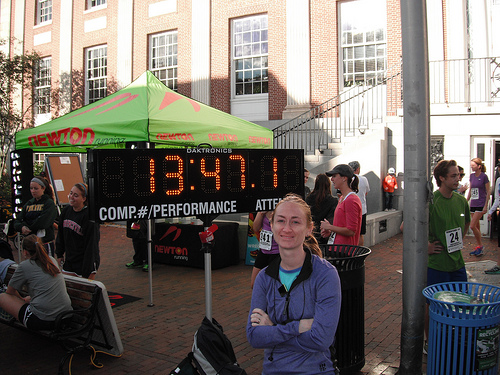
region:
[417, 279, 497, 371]
blue trash on street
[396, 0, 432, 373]
a long grey pole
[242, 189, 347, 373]
a lady in blue sweater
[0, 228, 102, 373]
a lady on bench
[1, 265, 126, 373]
a table leaning on bench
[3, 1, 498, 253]
a brick building with windows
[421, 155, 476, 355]
a man on green shirt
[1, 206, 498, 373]
sidewalk is of bricks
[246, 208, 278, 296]
a lady in purple shirt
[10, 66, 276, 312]
a green umbrella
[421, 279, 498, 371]
A blue trash bin.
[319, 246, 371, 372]
A black trash bin.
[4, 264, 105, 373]
A wooden and metal bench.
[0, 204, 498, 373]
Red bricks on the ground.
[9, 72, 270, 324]
A green and red event tent.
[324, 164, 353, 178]
A dark colored ball cap.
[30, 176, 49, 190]
A grey headband.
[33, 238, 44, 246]
A white hair tie.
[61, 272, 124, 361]
A white foldable table.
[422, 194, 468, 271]
A green short sleeved shirt.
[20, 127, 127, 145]
newton brand name on umbrella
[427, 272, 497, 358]
metal blue trash can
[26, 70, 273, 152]
green sponser umbrella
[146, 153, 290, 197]
time for a racer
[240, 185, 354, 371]
lady with a purple jacket on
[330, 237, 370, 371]
black trash can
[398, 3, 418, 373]
metal pole in brick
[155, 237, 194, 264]
newton brand name on table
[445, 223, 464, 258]
numer 24 racer tag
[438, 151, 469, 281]
man who is a racer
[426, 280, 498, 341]
this is a trash bin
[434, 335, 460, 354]
the bin is blue in color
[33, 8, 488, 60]
this is a building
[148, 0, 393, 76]
these are several windows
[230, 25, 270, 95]
the window is closed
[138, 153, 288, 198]
these are some digits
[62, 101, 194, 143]
this is an umbrella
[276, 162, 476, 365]
these are several people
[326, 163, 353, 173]
this is a cap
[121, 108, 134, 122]
the umbrella is green in color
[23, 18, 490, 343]
a busy street scene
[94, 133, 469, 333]
this young lady is smiling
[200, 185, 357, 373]
she is posing for a picture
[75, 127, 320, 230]
this is a digital clock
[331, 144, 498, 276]
these people are walking around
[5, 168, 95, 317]
these people are laughing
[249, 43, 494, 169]
this is a stairway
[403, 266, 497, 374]
a blue trash can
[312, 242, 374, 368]
a black trash can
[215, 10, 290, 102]
a window on the building